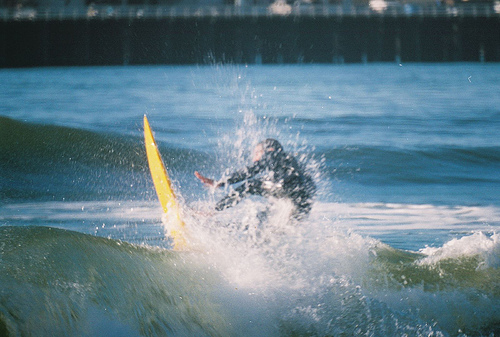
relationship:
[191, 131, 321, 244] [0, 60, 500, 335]
person in water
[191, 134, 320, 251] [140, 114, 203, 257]
person on surfboard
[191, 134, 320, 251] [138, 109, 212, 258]
person on surfboard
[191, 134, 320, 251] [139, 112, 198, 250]
person catching wave on surfboard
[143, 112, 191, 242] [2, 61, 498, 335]
surfboard in water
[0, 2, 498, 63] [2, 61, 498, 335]
bridge across water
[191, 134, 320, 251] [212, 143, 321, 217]
person wearing wetsuit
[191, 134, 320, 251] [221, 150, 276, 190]
person has arm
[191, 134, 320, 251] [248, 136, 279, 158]
person has head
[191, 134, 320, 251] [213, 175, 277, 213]
person has leg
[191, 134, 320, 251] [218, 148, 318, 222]
person wearing wetsuit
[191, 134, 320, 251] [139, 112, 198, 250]
person riding surfboard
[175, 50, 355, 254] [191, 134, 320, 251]
water splashing over person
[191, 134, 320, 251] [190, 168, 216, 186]
person has hand